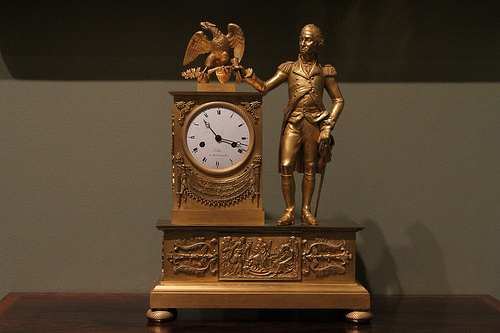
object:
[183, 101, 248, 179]
clock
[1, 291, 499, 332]
table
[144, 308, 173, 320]
foot pad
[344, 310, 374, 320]
foot pad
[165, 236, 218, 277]
design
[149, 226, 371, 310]
base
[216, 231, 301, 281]
design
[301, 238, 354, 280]
design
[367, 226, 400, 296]
shadow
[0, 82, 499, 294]
wall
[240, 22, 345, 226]
image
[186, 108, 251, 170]
face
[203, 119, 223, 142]
hand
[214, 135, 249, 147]
hand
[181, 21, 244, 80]
eagle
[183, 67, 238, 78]
branch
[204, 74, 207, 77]
claws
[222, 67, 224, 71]
claws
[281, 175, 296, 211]
sock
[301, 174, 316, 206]
sock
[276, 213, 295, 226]
shoe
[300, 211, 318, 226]
shoe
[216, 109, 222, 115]
roman numeral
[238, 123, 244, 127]
roman numeral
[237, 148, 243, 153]
roman numeral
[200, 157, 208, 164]
roman numeral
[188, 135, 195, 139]
roman numeral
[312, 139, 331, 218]
sword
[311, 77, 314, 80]
button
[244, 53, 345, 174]
jacket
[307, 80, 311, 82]
button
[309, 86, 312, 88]
button